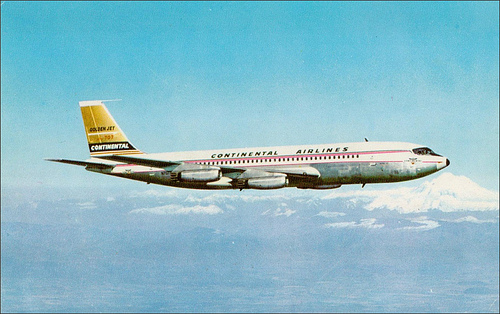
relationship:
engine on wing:
[172, 164, 226, 180] [96, 155, 318, 192]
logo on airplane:
[208, 144, 354, 159] [46, 99, 452, 190]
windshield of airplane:
[412, 146, 442, 157] [46, 99, 452, 190]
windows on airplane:
[190, 152, 362, 165] [46, 99, 452, 190]